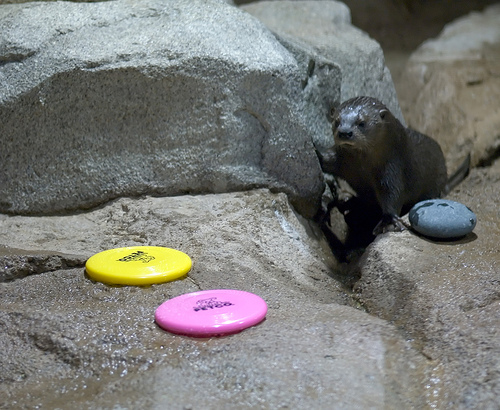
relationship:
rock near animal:
[0, 0, 500, 410] [320, 89, 479, 271]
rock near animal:
[5, 205, 396, 407] [320, 89, 479, 271]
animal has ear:
[333, 96, 448, 236] [374, 100, 392, 122]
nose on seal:
[337, 129, 354, 136] [313, 96, 448, 233]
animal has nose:
[333, 96, 448, 236] [329, 121, 356, 140]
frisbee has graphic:
[154, 290, 266, 340] [194, 297, 232, 311]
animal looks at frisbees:
[333, 96, 448, 236] [75, 235, 286, 372]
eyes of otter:
[335, 111, 369, 123] [328, 98, 455, 287]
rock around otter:
[0, 0, 500, 410] [315, 95, 470, 235]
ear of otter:
[376, 103, 386, 119] [326, 94, 476, 249]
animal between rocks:
[312, 93, 462, 268] [28, 22, 220, 152]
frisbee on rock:
[82, 243, 194, 288] [0, 263, 420, 409]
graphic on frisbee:
[194, 297, 232, 311] [154, 287, 269, 333]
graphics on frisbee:
[117, 250, 155, 260] [83, 245, 191, 285]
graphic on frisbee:
[188, 294, 244, 316] [70, 220, 195, 287]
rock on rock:
[0, 0, 500, 410] [341, 231, 474, 361]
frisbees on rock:
[75, 238, 269, 348] [3, 207, 303, 352]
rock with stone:
[0, 0, 500, 410] [405, 199, 475, 242]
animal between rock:
[333, 96, 448, 236] [0, 0, 500, 410]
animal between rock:
[333, 96, 448, 236] [356, 140, 498, 405]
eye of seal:
[355, 118, 367, 133] [309, 91, 465, 224]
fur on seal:
[359, 159, 406, 200] [299, 79, 436, 204]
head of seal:
[327, 101, 377, 158] [320, 93, 477, 225]